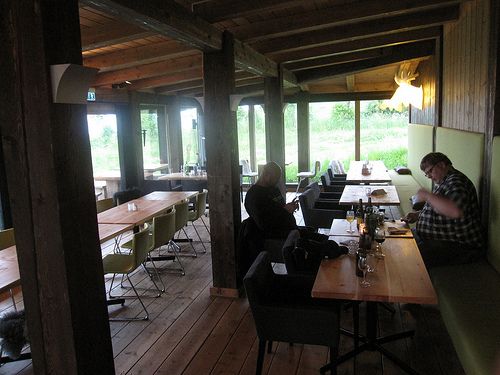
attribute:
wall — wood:
[408, 4, 499, 134]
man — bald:
[244, 160, 300, 238]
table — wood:
[97, 188, 200, 223]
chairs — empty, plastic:
[153, 187, 211, 276]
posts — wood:
[202, 26, 245, 296]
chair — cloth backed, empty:
[241, 252, 342, 375]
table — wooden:
[345, 159, 390, 182]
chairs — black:
[298, 162, 346, 229]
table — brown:
[309, 217, 440, 306]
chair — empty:
[299, 188, 345, 226]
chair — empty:
[297, 160, 322, 194]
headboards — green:
[403, 123, 500, 273]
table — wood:
[339, 182, 401, 208]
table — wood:
[1, 223, 136, 292]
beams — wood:
[81, 1, 296, 87]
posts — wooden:
[264, 77, 287, 203]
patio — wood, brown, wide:
[0, 190, 456, 375]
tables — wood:
[338, 161, 400, 206]